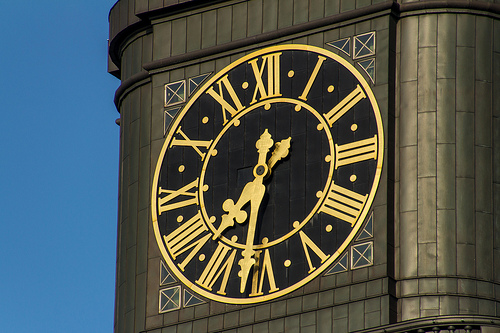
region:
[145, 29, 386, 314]
circular clock face on a tower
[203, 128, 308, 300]
two gold hands on a clock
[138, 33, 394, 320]
clock face with roman numerals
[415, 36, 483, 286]
verticle bricks on a column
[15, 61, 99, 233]
crisp bright blue sky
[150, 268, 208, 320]
decorate corner by a clock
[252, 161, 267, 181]
circle between two clock hands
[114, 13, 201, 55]
shadows cast from the top of the building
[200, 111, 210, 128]
golden cirlce on a clock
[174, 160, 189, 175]
golden circle on a clock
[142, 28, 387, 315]
clock face on side of building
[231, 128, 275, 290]
gold minute hand of the clock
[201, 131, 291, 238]
gold hour hand of the clock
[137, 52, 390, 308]
roman numeral hour markings on the clock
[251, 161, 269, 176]
black screw holding clock hands to face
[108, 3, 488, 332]
gray building clockface is on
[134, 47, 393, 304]
black background of clock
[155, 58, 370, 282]
gold dots on clockface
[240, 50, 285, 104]
roman numeral twelve on the clockface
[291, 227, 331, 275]
roman numeral five on the clockface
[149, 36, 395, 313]
Black and gold clock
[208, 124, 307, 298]
Two gold hands on the clock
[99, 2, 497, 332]
Gray clock tower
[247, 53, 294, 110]
Gold roman numeral number 12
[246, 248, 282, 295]
Gold number 6 on clock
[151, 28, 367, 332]
Beautiful black and gold clock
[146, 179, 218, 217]
Gold number 9 on the clock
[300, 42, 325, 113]
Gold number one on the clock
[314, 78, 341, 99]
Small gold dot on the clock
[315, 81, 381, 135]
Gold number two on the clock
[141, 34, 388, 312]
The clock face is black.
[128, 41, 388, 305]
The hands are gold.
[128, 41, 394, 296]
The numbers are gold.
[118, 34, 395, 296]
The numbers are Roman Numerals.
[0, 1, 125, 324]
The sky is clear blue.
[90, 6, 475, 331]
THe building is gray.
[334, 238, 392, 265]
The square is black.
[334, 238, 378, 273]
The X is in the square.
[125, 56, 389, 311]
The clock has dots.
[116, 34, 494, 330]
The clock is on the building.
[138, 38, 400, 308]
This is a clock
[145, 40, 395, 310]
This is a golden clock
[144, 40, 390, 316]
a black and golden clock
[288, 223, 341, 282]
This is a Roman number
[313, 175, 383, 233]
This is a Roman number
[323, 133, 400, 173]
This is a Roman number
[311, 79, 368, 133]
This is a Roman number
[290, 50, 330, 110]
This is a Roman number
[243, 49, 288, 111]
This is a Roman number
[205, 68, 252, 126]
This is a Roman number